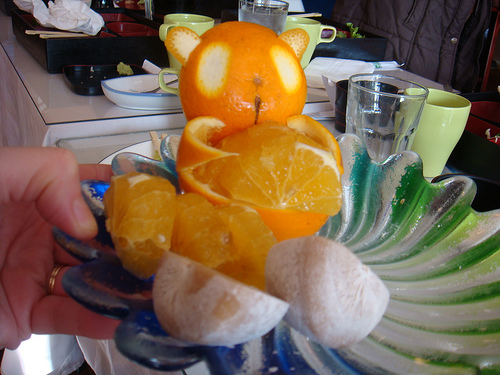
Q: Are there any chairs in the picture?
A: No, there are no chairs.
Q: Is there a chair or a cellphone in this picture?
A: No, there are no chairs or cell phones.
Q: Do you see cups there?
A: Yes, there is a cup.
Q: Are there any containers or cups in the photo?
A: Yes, there is a cup.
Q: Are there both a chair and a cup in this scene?
A: No, there is a cup but no chairs.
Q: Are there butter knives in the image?
A: No, there are no butter knives.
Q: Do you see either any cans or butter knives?
A: No, there are no butter knives or cans.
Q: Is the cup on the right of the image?
A: Yes, the cup is on the right of the image.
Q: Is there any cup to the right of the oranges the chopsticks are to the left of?
A: Yes, there is a cup to the right of the oranges.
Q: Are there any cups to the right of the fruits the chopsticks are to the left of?
A: Yes, there is a cup to the right of the oranges.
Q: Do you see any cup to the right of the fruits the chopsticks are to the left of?
A: Yes, there is a cup to the right of the oranges.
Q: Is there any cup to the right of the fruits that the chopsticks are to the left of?
A: Yes, there is a cup to the right of the oranges.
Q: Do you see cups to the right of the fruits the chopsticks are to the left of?
A: Yes, there is a cup to the right of the oranges.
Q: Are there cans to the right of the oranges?
A: No, there is a cup to the right of the oranges.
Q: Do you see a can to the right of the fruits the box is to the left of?
A: No, there is a cup to the right of the oranges.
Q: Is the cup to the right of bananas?
A: No, the cup is to the right of the oranges.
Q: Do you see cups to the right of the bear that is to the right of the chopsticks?
A: Yes, there is a cup to the right of the bear.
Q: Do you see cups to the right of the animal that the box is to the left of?
A: Yes, there is a cup to the right of the bear.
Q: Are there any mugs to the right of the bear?
A: No, there is a cup to the right of the bear.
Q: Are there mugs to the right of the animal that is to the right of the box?
A: No, there is a cup to the right of the bear.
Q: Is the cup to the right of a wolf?
A: No, the cup is to the right of the bear.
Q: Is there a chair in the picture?
A: No, there are no chairs.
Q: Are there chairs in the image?
A: No, there are no chairs.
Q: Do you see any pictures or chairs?
A: No, there are no chairs or pictures.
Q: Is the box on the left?
A: Yes, the box is on the left of the image.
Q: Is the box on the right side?
A: No, the box is on the left of the image.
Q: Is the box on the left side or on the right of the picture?
A: The box is on the left of the image.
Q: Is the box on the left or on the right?
A: The box is on the left of the image.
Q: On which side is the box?
A: The box is on the left of the image.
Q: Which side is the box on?
A: The box is on the left of the image.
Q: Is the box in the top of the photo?
A: Yes, the box is in the top of the image.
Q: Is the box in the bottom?
A: No, the box is in the top of the image.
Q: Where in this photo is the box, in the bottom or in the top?
A: The box is in the top of the image.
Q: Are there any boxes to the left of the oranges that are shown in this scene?
A: Yes, there is a box to the left of the oranges.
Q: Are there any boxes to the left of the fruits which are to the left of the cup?
A: Yes, there is a box to the left of the oranges.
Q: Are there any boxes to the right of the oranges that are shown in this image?
A: No, the box is to the left of the oranges.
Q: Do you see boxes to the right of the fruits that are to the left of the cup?
A: No, the box is to the left of the oranges.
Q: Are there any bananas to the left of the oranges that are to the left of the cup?
A: No, there is a box to the left of the oranges.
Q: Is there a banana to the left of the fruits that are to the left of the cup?
A: No, there is a box to the left of the oranges.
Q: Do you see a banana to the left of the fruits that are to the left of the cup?
A: No, there is a box to the left of the oranges.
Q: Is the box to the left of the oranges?
A: Yes, the box is to the left of the oranges.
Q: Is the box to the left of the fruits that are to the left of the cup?
A: Yes, the box is to the left of the oranges.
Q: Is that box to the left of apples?
A: No, the box is to the left of the oranges.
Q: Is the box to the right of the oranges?
A: No, the box is to the left of the oranges.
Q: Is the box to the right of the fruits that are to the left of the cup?
A: No, the box is to the left of the oranges.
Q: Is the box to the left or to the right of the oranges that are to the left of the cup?
A: The box is to the left of the oranges.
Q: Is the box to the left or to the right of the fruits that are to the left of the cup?
A: The box is to the left of the oranges.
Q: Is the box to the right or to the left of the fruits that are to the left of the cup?
A: The box is to the left of the oranges.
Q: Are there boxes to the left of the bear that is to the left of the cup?
A: Yes, there is a box to the left of the bear.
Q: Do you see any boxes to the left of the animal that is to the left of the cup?
A: Yes, there is a box to the left of the bear.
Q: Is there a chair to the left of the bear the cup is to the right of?
A: No, there is a box to the left of the bear.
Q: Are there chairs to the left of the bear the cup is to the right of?
A: No, there is a box to the left of the bear.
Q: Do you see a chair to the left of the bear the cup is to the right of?
A: No, there is a box to the left of the bear.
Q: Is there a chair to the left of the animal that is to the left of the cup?
A: No, there is a box to the left of the bear.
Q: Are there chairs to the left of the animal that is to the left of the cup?
A: No, there is a box to the left of the bear.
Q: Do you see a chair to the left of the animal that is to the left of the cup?
A: No, there is a box to the left of the bear.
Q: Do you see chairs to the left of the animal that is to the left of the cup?
A: No, there is a box to the left of the bear.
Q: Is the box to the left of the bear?
A: Yes, the box is to the left of the bear.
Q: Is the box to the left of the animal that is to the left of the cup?
A: Yes, the box is to the left of the bear.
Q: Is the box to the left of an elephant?
A: No, the box is to the left of the bear.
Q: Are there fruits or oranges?
A: Yes, there are oranges.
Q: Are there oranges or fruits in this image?
A: Yes, there are oranges.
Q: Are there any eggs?
A: No, there are no eggs.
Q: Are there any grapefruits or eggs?
A: No, there are no eggs or grapefruits.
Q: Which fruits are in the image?
A: The fruits are oranges.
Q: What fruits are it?
A: The fruits are oranges.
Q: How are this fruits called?
A: These are oranges.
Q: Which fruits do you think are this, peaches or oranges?
A: These are oranges.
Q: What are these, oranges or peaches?
A: These are oranges.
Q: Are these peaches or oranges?
A: These are oranges.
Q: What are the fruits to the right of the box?
A: The fruits are oranges.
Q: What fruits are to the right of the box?
A: The fruits are oranges.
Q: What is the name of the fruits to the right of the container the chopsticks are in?
A: The fruits are oranges.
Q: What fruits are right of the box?
A: The fruits are oranges.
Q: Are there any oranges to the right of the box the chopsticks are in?
A: Yes, there are oranges to the right of the box.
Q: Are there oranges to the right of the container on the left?
A: Yes, there are oranges to the right of the box.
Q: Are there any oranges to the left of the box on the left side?
A: No, the oranges are to the right of the box.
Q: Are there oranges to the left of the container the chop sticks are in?
A: No, the oranges are to the right of the box.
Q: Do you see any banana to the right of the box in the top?
A: No, there are oranges to the right of the box.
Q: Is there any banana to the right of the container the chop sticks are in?
A: No, there are oranges to the right of the box.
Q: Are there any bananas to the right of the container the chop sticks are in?
A: No, there are oranges to the right of the box.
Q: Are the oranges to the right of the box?
A: Yes, the oranges are to the right of the box.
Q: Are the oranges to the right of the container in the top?
A: Yes, the oranges are to the right of the box.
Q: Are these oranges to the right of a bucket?
A: No, the oranges are to the right of the box.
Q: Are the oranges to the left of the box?
A: No, the oranges are to the right of the box.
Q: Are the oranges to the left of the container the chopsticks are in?
A: No, the oranges are to the right of the box.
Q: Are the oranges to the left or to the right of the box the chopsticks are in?
A: The oranges are to the right of the box.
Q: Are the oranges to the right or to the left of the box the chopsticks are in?
A: The oranges are to the right of the box.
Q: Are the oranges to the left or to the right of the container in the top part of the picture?
A: The oranges are to the right of the box.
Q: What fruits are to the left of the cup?
A: The fruits are oranges.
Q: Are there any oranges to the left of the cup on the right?
A: Yes, there are oranges to the left of the cup.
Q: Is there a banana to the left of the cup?
A: No, there are oranges to the left of the cup.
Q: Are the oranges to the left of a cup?
A: Yes, the oranges are to the left of a cup.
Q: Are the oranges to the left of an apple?
A: No, the oranges are to the left of a cup.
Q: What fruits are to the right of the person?
A: The fruits are oranges.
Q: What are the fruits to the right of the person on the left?
A: The fruits are oranges.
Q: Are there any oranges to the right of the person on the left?
A: Yes, there are oranges to the right of the person.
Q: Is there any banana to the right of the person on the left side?
A: No, there are oranges to the right of the person.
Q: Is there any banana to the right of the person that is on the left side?
A: No, there are oranges to the right of the person.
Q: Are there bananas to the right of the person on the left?
A: No, there are oranges to the right of the person.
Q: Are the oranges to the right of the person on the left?
A: Yes, the oranges are to the right of the person.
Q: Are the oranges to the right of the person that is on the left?
A: Yes, the oranges are to the right of the person.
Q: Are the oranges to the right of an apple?
A: No, the oranges are to the right of the person.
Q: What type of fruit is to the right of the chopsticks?
A: The fruits are oranges.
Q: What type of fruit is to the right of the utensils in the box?
A: The fruits are oranges.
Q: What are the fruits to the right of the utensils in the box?
A: The fruits are oranges.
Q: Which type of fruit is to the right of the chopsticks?
A: The fruits are oranges.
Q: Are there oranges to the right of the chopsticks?
A: Yes, there are oranges to the right of the chopsticks.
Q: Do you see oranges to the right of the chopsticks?
A: Yes, there are oranges to the right of the chopsticks.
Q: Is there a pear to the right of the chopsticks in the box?
A: No, there are oranges to the right of the chopsticks.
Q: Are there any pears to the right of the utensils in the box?
A: No, there are oranges to the right of the chopsticks.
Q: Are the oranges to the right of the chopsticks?
A: Yes, the oranges are to the right of the chopsticks.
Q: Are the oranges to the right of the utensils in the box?
A: Yes, the oranges are to the right of the chopsticks.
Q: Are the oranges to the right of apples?
A: No, the oranges are to the right of the chopsticks.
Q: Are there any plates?
A: Yes, there is a plate.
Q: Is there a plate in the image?
A: Yes, there is a plate.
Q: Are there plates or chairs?
A: Yes, there is a plate.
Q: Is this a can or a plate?
A: This is a plate.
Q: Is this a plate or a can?
A: This is a plate.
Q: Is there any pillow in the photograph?
A: No, there are no pillows.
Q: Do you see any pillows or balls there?
A: No, there are no pillows or balls.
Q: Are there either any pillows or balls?
A: No, there are no pillows or balls.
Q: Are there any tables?
A: Yes, there is a table.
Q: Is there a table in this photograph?
A: Yes, there is a table.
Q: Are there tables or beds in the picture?
A: Yes, there is a table.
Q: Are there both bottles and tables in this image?
A: No, there is a table but no bottles.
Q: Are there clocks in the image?
A: No, there are no clocks.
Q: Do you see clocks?
A: No, there are no clocks.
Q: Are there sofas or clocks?
A: No, there are no clocks or sofas.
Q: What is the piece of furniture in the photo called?
A: The piece of furniture is a table.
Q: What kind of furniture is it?
A: The piece of furniture is a table.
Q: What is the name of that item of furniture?
A: This is a table.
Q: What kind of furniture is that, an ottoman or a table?
A: This is a table.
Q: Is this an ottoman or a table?
A: This is a table.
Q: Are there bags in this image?
A: No, there are no bags.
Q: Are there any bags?
A: No, there are no bags.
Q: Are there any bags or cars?
A: No, there are no bags or cars.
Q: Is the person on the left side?
A: Yes, the person is on the left of the image.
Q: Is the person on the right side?
A: No, the person is on the left of the image.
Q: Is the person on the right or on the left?
A: The person is on the left of the image.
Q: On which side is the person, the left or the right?
A: The person is on the left of the image.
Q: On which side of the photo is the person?
A: The person is on the left of the image.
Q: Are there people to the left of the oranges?
A: Yes, there is a person to the left of the oranges.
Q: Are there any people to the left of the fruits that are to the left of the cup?
A: Yes, there is a person to the left of the oranges.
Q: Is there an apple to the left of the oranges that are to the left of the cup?
A: No, there is a person to the left of the oranges.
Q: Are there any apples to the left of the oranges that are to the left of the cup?
A: No, there is a person to the left of the oranges.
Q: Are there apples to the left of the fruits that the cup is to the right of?
A: No, there is a person to the left of the oranges.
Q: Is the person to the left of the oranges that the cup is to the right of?
A: Yes, the person is to the left of the oranges.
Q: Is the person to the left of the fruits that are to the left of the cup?
A: Yes, the person is to the left of the oranges.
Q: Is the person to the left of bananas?
A: No, the person is to the left of the oranges.